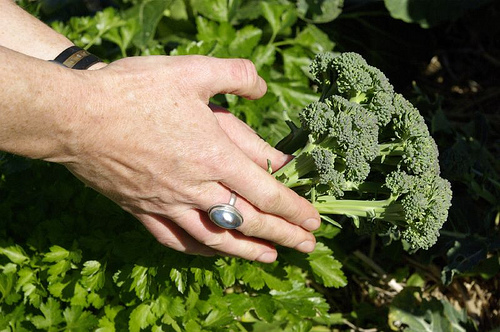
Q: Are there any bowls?
A: No, there are no bowls.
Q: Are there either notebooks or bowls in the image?
A: No, there are no bowls or notebooks.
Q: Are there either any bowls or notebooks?
A: No, there are no bowls or notebooks.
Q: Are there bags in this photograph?
A: No, there are no bags.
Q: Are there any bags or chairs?
A: No, there are no bags or chairs.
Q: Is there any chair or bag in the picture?
A: No, there are no bags or chairs.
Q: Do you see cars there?
A: No, there are no cars.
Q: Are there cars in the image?
A: No, there are no cars.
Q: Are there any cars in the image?
A: No, there are no cars.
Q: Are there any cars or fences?
A: No, there are no cars or fences.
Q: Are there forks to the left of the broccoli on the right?
A: No, there is a person to the left of the broccoli.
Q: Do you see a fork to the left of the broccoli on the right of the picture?
A: No, there is a person to the left of the broccoli.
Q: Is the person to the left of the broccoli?
A: Yes, the person is to the left of the broccoli.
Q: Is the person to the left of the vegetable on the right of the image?
A: Yes, the person is to the left of the broccoli.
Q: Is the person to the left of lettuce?
A: No, the person is to the left of the broccoli.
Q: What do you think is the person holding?
A: The person is holding the broccoli.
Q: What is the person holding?
A: The person is holding the broccoli.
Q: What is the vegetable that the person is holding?
A: The vegetable is broccoli.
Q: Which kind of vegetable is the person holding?
A: The person is holding the broccoli.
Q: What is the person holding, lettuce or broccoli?
A: The person is holding broccoli.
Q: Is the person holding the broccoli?
A: Yes, the person is holding the broccoli.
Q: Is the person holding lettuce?
A: No, the person is holding the broccoli.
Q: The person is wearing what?
A: The person is wearing a watch.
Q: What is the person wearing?
A: The person is wearing a watch.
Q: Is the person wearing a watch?
A: Yes, the person is wearing a watch.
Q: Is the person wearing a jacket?
A: No, the person is wearing a watch.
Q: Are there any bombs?
A: No, there are no bombs.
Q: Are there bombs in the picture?
A: No, there are no bombs.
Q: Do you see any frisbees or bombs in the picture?
A: No, there are no bombs or frisbees.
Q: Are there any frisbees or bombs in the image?
A: No, there are no bombs or frisbees.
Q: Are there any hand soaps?
A: No, there are no hand soaps.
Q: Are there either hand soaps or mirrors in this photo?
A: No, there are no hand soaps or mirrors.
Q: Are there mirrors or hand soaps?
A: No, there are no hand soaps or mirrors.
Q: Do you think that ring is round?
A: Yes, the ring is round.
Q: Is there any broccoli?
A: Yes, there is broccoli.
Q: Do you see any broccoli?
A: Yes, there is broccoli.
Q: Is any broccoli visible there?
A: Yes, there is broccoli.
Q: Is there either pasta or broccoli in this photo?
A: Yes, there is broccoli.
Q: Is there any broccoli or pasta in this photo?
A: Yes, there is broccoli.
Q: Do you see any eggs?
A: No, there are no eggs.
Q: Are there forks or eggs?
A: No, there are no eggs or forks.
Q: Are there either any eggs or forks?
A: No, there are no eggs or forks.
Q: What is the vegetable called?
A: The vegetable is broccoli.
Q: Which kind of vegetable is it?
A: The vegetable is broccoli.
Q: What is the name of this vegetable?
A: This is broccoli.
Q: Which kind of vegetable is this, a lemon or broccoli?
A: This is broccoli.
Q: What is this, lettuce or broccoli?
A: This is broccoli.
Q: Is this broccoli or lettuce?
A: This is broccoli.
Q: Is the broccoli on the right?
A: Yes, the broccoli is on the right of the image.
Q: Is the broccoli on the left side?
A: No, the broccoli is on the right of the image.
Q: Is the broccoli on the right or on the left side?
A: The broccoli is on the right of the image.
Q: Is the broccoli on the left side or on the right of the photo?
A: The broccoli is on the right of the image.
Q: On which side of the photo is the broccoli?
A: The broccoli is on the right of the image.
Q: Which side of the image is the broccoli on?
A: The broccoli is on the right of the image.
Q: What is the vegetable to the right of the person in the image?
A: The vegetable is broccoli.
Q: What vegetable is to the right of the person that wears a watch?
A: The vegetable is broccoli.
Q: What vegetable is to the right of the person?
A: The vegetable is broccoli.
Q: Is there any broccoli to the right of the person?
A: Yes, there is broccoli to the right of the person.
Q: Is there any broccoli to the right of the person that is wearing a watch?
A: Yes, there is broccoli to the right of the person.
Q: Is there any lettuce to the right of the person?
A: No, there is broccoli to the right of the person.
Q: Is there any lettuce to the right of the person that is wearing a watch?
A: No, there is broccoli to the right of the person.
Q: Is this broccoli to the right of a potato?
A: No, the broccoli is to the right of the person.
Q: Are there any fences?
A: No, there are no fences.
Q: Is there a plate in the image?
A: No, there are no plates.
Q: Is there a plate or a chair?
A: No, there are no plates or chairs.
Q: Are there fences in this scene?
A: No, there are no fences.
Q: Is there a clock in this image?
A: No, there are no clocks.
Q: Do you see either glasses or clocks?
A: No, there are no clocks or glasses.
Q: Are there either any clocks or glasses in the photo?
A: No, there are no clocks or glasses.